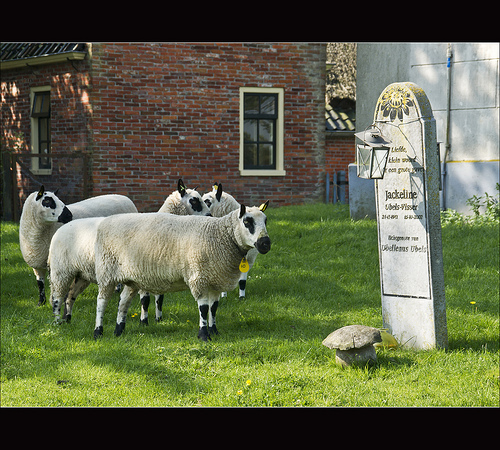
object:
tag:
[239, 257, 250, 273]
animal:
[93, 199, 271, 341]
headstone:
[353, 81, 449, 351]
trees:
[438, 63, 479, 149]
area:
[0, 203, 500, 409]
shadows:
[58, 342, 217, 398]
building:
[347, 42, 500, 219]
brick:
[0, 43, 355, 223]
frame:
[239, 86, 287, 177]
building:
[0, 42, 325, 224]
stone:
[371, 82, 449, 353]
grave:
[322, 324, 382, 368]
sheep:
[19, 178, 272, 342]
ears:
[239, 204, 246, 219]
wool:
[125, 224, 174, 246]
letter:
[385, 189, 417, 201]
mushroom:
[322, 325, 383, 367]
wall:
[91, 28, 328, 213]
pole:
[441, 42, 453, 211]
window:
[29, 86, 50, 176]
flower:
[237, 380, 251, 395]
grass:
[0, 183, 500, 402]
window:
[239, 86, 286, 176]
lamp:
[354, 122, 391, 179]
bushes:
[440, 182, 500, 225]